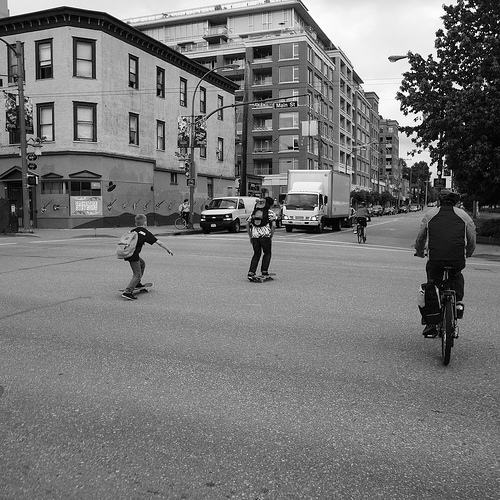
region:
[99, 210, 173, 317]
person riding a skateboard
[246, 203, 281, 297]
person riding a skateboard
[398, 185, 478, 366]
person riding a bicycle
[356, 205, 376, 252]
person riding a bicycle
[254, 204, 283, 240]
person is wearing a backpack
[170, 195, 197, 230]
person on sidewalk with a bike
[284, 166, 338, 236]
truck is stopped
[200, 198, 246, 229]
van is stopped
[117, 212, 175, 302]
A boy riding a skateboard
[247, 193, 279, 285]
A person on a skateboard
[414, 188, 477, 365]
Someone who is biking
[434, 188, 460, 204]
A bike helmet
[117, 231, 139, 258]
A light colored backpack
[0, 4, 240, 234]
A three story building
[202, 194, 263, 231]
A white van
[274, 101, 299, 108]
A street sign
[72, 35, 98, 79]
A third floor window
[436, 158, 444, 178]
A three color street light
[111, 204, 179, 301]
a boy on a skateboard wearing a back pack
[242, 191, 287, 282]
a boy on a skateboard wearing a back pack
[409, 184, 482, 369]
a boy on a bike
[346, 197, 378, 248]
a boy on a bike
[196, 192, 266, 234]
a white van stopped on the street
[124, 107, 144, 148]
the window of a building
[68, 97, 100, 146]
the window of a building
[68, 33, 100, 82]
the window of a building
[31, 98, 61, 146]
the window of a building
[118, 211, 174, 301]
a skateboarder in street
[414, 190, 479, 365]
a man riding bicycle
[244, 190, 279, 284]
a person riding a skateboard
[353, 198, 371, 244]
a man riding a bicycle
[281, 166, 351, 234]
a white commercial truck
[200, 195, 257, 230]
a parked white van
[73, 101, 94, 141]
a building double hung window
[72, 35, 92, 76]
a building double hung window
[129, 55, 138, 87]
a building double hung window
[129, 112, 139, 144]
a building double hung window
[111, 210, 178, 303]
boy on skateboard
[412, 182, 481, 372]
person on bicycle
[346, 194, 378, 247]
a person riding bicycle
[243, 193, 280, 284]
a person on skateboard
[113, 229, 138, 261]
backpack the boy is carrying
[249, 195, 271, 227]
a backpack the guy is carrying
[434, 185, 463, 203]
a helmet the person is wearing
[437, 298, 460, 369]
rear wheel of the bicycle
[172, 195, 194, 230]
person on bicycle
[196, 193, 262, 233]
a white van on road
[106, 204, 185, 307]
Boy riding a skateboard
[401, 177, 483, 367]
Man riding a bike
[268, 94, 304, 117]
Street sign on a post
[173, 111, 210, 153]
Sign on a post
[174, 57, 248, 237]
Light post by a building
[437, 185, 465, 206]
Helmet on a man's head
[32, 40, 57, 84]
Open window on a building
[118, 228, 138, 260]
Back pack on blonde haired boy.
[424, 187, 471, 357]
Man riding a bicycle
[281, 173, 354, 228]
White delivery truck on street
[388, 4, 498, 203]
Large tree has lots of leaves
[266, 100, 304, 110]
Sign says Main Street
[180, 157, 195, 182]
Traffic light is on pole